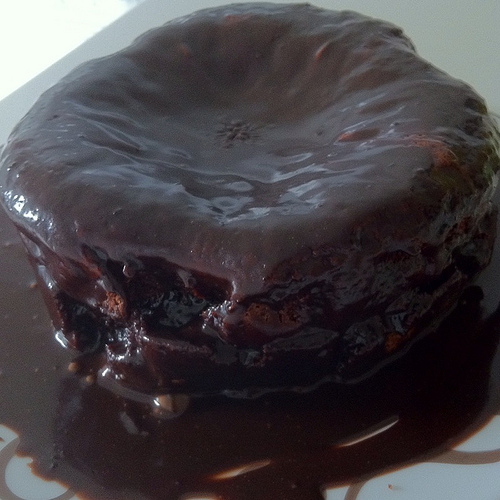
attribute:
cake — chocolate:
[18, 121, 429, 454]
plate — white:
[224, 420, 407, 469]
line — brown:
[331, 405, 481, 498]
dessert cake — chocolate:
[26, 30, 435, 460]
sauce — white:
[108, 308, 279, 484]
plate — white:
[180, 368, 440, 493]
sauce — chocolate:
[31, 414, 402, 498]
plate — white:
[183, 380, 452, 483]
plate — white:
[187, 389, 438, 493]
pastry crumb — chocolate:
[52, 289, 248, 360]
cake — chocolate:
[21, 68, 494, 440]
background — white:
[22, 12, 93, 53]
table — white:
[1, 6, 98, 116]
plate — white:
[250, 417, 417, 480]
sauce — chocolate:
[191, 344, 443, 496]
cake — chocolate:
[0, 0, 446, 485]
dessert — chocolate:
[22, 17, 490, 493]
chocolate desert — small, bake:
[4, 5, 484, 424]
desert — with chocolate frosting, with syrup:
[7, 1, 471, 418]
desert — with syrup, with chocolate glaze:
[9, 2, 480, 497]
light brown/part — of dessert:
[104, 292, 124, 313]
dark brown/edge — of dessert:
[213, 277, 403, 347]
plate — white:
[201, 411, 417, 486]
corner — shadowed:
[125, 4, 497, 124]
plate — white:
[4, 4, 499, 496]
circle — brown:
[2, 422, 87, 497]